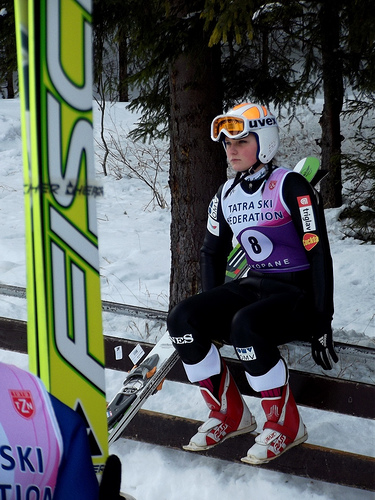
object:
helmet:
[210, 102, 280, 164]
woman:
[166, 101, 339, 464]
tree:
[91, 1, 303, 311]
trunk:
[164, 10, 228, 321]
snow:
[0, 62, 374, 230]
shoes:
[240, 357, 308, 465]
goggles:
[210, 112, 249, 141]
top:
[199, 165, 338, 370]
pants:
[167, 270, 314, 376]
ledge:
[0, 284, 374, 492]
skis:
[106, 155, 330, 447]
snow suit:
[167, 165, 339, 377]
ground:
[0, 93, 374, 351]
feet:
[240, 419, 309, 464]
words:
[45, 0, 106, 397]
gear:
[14, 0, 109, 488]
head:
[210, 102, 279, 172]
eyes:
[238, 140, 248, 145]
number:
[247, 235, 262, 254]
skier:
[0, 362, 121, 499]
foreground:
[0, 286, 375, 499]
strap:
[223, 161, 261, 200]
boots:
[181, 342, 257, 452]